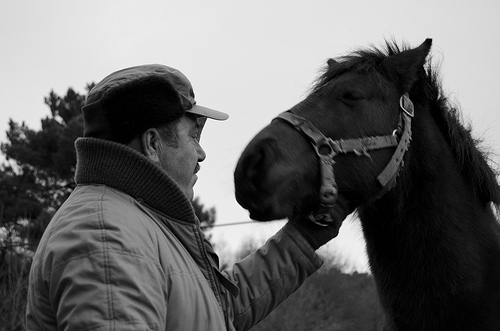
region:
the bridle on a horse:
[265, 86, 433, 208]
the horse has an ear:
[395, 30, 435, 80]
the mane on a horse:
[422, 59, 497, 215]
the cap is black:
[70, 55, 238, 136]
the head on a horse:
[222, 33, 479, 292]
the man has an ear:
[139, 120, 171, 166]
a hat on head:
[81, 63, 231, 144]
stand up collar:
[71, 133, 197, 227]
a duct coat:
[23, 136, 327, 329]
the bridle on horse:
[276, 88, 416, 225]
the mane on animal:
[306, 33, 498, 223]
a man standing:
[21, 60, 326, 327]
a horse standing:
[230, 31, 498, 329]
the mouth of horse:
[233, 167, 303, 219]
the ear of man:
[139, 123, 166, 165]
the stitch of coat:
[92, 183, 120, 328]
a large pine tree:
[0, 80, 217, 251]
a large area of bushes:
[0, 235, 386, 329]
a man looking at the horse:
[25, 63, 355, 329]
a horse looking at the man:
[233, 25, 498, 329]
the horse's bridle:
[271, 90, 413, 225]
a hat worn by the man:
[82, 64, 229, 144]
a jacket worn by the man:
[24, 136, 355, 329]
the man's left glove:
[287, 209, 355, 250]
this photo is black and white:
[22, 29, 481, 259]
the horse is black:
[250, 42, 463, 260]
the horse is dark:
[265, 76, 493, 305]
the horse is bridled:
[297, 92, 423, 222]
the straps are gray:
[286, 83, 412, 202]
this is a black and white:
[39, 49, 341, 274]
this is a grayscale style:
[9, 40, 442, 257]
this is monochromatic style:
[18, 22, 338, 252]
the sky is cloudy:
[189, 29, 255, 85]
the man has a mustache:
[38, 72, 230, 269]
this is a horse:
[206, 0, 498, 329]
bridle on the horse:
[222, 36, 450, 238]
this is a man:
[25, 21, 322, 323]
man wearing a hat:
[61, 51, 227, 158]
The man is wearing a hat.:
[76, 60, 221, 136]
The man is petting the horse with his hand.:
[273, 210, 341, 262]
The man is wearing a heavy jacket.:
[41, 140, 321, 327]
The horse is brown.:
[229, 41, 495, 329]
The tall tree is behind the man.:
[7, 70, 91, 273]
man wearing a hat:
[74, 59, 230, 140]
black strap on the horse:
[260, 93, 432, 204]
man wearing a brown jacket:
[13, 133, 324, 328]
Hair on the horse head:
[332, 41, 499, 181]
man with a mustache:
[185, 153, 207, 175]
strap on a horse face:
[262, 93, 427, 213]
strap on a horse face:
[306, 121, 343, 217]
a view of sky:
[209, 22, 266, 72]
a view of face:
[251, 90, 399, 213]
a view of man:
[90, 43, 238, 203]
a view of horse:
[229, 37, 392, 207]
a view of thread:
[287, 146, 369, 208]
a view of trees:
[25, 74, 89, 167]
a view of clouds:
[233, 18, 285, 77]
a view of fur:
[321, 70, 389, 95]